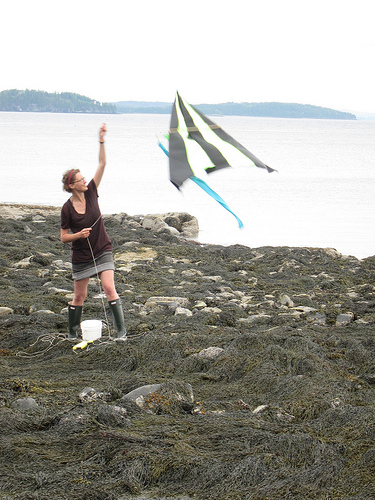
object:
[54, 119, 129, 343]
woman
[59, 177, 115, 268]
shirt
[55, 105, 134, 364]
woman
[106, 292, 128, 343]
black boot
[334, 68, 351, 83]
ground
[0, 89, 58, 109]
trees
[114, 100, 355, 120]
land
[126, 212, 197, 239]
rocks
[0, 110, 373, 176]
water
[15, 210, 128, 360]
string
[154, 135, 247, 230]
tail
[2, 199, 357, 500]
cliff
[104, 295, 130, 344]
woman's boot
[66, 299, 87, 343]
woman's boot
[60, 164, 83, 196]
hair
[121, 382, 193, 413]
rock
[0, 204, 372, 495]
ground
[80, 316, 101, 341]
bucket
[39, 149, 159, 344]
woman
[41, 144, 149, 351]
woman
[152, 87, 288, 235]
kite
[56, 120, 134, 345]
girl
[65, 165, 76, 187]
headband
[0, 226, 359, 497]
land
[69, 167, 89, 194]
face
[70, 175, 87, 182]
glasses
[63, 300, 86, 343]
boot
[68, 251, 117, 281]
skirt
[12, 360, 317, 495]
ground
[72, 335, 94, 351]
handle